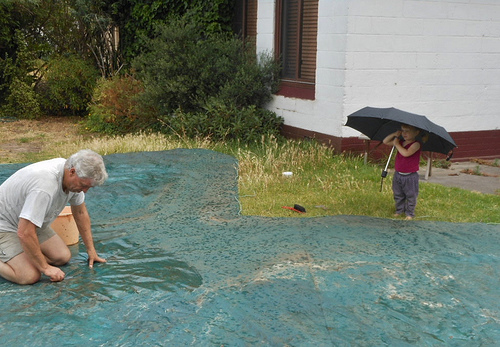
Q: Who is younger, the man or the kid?
A: The kid is younger than the man.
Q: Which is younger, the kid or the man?
A: The kid is younger than the man.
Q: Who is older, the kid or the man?
A: The man is older than the kid.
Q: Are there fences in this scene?
A: No, there are no fences.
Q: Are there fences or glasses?
A: No, there are no fences or glasses.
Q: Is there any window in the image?
A: Yes, there is a window.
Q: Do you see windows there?
A: Yes, there is a window.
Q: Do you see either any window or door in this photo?
A: Yes, there is a window.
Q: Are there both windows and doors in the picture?
A: No, there is a window but no doors.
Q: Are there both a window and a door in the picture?
A: No, there is a window but no doors.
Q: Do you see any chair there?
A: No, there are no chairs.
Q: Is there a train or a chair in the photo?
A: No, there are no chairs or trains.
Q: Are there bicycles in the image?
A: No, there are no bicycles.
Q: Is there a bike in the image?
A: No, there are no bikes.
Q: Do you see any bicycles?
A: No, there are no bicycles.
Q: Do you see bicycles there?
A: No, there are no bicycles.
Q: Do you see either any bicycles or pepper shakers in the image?
A: No, there are no bicycles or pepper shakers.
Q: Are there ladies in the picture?
A: No, there are no ladies.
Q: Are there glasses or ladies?
A: No, there are no ladies or glasses.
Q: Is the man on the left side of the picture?
A: Yes, the man is on the left of the image.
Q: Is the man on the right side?
A: No, the man is on the left of the image.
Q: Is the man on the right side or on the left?
A: The man is on the left of the image.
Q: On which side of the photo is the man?
A: The man is on the left of the image.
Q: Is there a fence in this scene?
A: No, there are no fences.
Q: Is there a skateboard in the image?
A: No, there are no skateboards.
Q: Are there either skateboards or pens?
A: No, there are no skateboards or pens.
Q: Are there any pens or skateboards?
A: No, there are no skateboards or pens.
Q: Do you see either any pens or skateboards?
A: No, there are no skateboards or pens.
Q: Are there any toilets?
A: No, there are no toilets.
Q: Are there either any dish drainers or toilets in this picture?
A: No, there are no toilets or dish drainers.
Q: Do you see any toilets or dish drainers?
A: No, there are no toilets or dish drainers.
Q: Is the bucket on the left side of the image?
A: Yes, the bucket is on the left of the image.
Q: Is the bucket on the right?
A: No, the bucket is on the left of the image.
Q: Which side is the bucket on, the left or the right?
A: The bucket is on the left of the image.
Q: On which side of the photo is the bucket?
A: The bucket is on the left of the image.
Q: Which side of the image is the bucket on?
A: The bucket is on the left of the image.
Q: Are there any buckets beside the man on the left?
A: Yes, there is a bucket beside the man.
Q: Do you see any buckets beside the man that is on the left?
A: Yes, there is a bucket beside the man.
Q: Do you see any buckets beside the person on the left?
A: Yes, there is a bucket beside the man.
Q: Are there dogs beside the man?
A: No, there is a bucket beside the man.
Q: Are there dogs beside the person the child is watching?
A: No, there is a bucket beside the man.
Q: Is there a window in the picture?
A: Yes, there is a window.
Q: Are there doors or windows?
A: Yes, there is a window.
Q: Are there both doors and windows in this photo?
A: No, there is a window but no doors.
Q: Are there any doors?
A: No, there are no doors.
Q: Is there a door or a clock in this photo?
A: No, there are no doors or clocks.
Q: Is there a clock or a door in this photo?
A: No, there are no doors or clocks.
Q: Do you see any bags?
A: No, there are no bags.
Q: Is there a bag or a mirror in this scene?
A: No, there are no bags or mirrors.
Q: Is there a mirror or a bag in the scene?
A: No, there are no bags or mirrors.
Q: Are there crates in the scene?
A: No, there are no crates.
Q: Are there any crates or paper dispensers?
A: No, there are no crates or paper dispensers.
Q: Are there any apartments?
A: No, there are no apartments.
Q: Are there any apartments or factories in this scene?
A: No, there are no apartments or factories.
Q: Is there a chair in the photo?
A: No, there are no chairs.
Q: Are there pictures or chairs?
A: No, there are no chairs or pictures.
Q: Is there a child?
A: Yes, there is a child.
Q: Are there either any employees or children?
A: Yes, there is a child.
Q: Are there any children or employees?
A: Yes, there is a child.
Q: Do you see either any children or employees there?
A: Yes, there is a child.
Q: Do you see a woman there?
A: No, there are no women.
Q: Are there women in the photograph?
A: No, there are no women.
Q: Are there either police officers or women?
A: No, there are no women or police officers.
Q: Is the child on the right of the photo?
A: Yes, the child is on the right of the image.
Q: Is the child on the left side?
A: No, the child is on the right of the image.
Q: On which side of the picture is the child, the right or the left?
A: The child is on the right of the image.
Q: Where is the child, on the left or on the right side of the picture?
A: The child is on the right of the image.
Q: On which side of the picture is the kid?
A: The kid is on the right of the image.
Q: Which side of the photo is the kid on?
A: The kid is on the right of the image.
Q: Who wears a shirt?
A: The child wears a shirt.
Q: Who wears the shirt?
A: The child wears a shirt.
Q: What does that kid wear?
A: The kid wears a shirt.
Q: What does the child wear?
A: The kid wears a shirt.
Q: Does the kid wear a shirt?
A: Yes, the kid wears a shirt.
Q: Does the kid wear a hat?
A: No, the kid wears a shirt.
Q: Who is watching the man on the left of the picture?
A: The kid is watching the man.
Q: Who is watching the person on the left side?
A: The kid is watching the man.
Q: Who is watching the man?
A: The kid is watching the man.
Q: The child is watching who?
A: The child is watching the man.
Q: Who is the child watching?
A: The child is watching the man.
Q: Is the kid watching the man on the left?
A: Yes, the kid is watching the man.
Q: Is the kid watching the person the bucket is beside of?
A: Yes, the kid is watching the man.